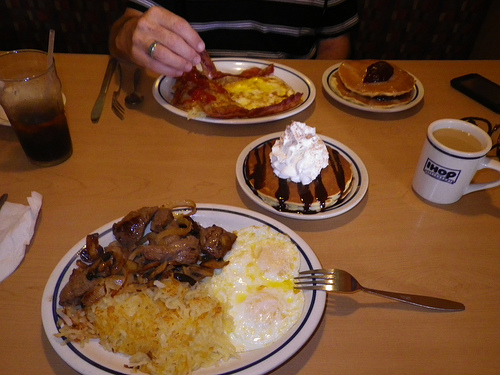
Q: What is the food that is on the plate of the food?
A: The food is eggs.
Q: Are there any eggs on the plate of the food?
A: Yes, there are eggs on the plate.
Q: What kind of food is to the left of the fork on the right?
A: The food is eggs.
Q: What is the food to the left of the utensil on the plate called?
A: The food is eggs.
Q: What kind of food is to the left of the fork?
A: The food is eggs.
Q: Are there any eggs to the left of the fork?
A: Yes, there are eggs to the left of the fork.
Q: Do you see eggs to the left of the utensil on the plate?
A: Yes, there are eggs to the left of the fork.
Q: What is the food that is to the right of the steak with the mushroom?
A: The food is eggs.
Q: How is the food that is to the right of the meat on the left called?
A: The food is eggs.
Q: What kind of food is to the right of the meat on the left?
A: The food is eggs.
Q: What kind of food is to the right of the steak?
A: The food is eggs.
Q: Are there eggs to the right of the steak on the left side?
A: Yes, there are eggs to the right of the steak.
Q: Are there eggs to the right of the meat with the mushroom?
A: Yes, there are eggs to the right of the steak.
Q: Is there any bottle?
A: No, there are no bottles.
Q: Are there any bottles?
A: No, there are no bottles.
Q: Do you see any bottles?
A: No, there are no bottles.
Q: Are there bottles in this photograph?
A: No, there are no bottles.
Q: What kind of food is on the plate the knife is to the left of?
A: The food is eggs.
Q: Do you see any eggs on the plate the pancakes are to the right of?
A: Yes, there are eggs on the plate.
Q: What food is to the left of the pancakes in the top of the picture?
A: The food is eggs.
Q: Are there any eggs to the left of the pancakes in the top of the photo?
A: Yes, there are eggs to the left of the pancakes.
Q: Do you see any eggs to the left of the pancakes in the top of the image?
A: Yes, there are eggs to the left of the pancakes.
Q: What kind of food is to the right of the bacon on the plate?
A: The food is eggs.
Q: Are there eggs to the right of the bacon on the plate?
A: Yes, there are eggs to the right of the bacon.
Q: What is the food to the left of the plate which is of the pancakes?
A: The food is eggs.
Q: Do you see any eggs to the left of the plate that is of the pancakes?
A: Yes, there are eggs to the left of the plate.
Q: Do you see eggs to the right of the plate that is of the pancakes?
A: No, the eggs are to the left of the plate.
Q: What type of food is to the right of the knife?
A: The food is eggs.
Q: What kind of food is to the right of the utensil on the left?
A: The food is eggs.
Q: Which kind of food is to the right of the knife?
A: The food is eggs.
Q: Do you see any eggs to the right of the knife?
A: Yes, there are eggs to the right of the knife.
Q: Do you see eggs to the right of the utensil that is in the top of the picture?
A: Yes, there are eggs to the right of the knife.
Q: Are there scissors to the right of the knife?
A: No, there are eggs to the right of the knife.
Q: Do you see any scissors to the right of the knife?
A: No, there are eggs to the right of the knife.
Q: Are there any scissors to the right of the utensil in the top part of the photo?
A: No, there are eggs to the right of the knife.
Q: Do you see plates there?
A: Yes, there is a plate.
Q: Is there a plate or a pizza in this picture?
A: Yes, there is a plate.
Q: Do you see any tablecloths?
A: No, there are no tablecloths.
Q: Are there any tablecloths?
A: No, there are no tablecloths.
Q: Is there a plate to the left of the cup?
A: Yes, there is a plate to the left of the cup.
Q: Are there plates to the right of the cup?
A: No, the plate is to the left of the cup.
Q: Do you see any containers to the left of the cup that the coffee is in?
A: No, there is a plate to the left of the cup.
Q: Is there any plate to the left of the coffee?
A: Yes, there is a plate to the left of the coffee.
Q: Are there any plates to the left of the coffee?
A: Yes, there is a plate to the left of the coffee.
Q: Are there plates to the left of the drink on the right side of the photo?
A: Yes, there is a plate to the left of the coffee.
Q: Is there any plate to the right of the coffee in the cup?
A: No, the plate is to the left of the coffee.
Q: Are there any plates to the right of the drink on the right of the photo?
A: No, the plate is to the left of the coffee.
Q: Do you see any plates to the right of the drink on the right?
A: No, the plate is to the left of the coffee.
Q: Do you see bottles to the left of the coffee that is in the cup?
A: No, there is a plate to the left of the coffee.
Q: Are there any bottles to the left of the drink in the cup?
A: No, there is a plate to the left of the coffee.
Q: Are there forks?
A: Yes, there is a fork.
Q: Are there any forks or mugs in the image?
A: Yes, there is a fork.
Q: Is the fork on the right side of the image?
A: Yes, the fork is on the right of the image.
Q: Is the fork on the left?
A: No, the fork is on the right of the image.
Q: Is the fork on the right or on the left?
A: The fork is on the right of the image.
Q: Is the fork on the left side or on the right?
A: The fork is on the right of the image.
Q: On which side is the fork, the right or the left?
A: The fork is on the right of the image.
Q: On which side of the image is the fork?
A: The fork is on the right of the image.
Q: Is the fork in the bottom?
A: Yes, the fork is in the bottom of the image.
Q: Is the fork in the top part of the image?
A: No, the fork is in the bottom of the image.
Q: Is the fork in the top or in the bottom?
A: The fork is in the bottom of the image.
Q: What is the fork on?
A: The fork is on the plate.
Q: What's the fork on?
A: The fork is on the plate.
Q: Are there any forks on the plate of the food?
A: Yes, there is a fork on the plate.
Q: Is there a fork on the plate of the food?
A: Yes, there is a fork on the plate.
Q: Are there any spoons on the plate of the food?
A: No, there is a fork on the plate.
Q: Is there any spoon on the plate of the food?
A: No, there is a fork on the plate.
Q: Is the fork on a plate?
A: Yes, the fork is on a plate.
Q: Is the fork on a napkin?
A: No, the fork is on a plate.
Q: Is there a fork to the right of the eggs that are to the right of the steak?
A: Yes, there is a fork to the right of the eggs.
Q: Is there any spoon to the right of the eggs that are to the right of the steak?
A: No, there is a fork to the right of the eggs.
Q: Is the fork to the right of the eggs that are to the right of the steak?
A: Yes, the fork is to the right of the eggs.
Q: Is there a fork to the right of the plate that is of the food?
A: Yes, there is a fork to the right of the plate.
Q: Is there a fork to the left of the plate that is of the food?
A: No, the fork is to the right of the plate.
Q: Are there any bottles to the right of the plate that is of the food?
A: No, there is a fork to the right of the plate.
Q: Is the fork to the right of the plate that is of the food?
A: Yes, the fork is to the right of the plate.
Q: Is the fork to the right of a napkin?
A: No, the fork is to the right of the plate.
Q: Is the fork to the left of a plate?
A: No, the fork is to the right of a plate.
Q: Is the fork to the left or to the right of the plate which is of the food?
A: The fork is to the right of the plate.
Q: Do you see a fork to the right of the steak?
A: Yes, there is a fork to the right of the steak.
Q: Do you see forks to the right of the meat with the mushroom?
A: Yes, there is a fork to the right of the steak.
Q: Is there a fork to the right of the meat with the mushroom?
A: Yes, there is a fork to the right of the steak.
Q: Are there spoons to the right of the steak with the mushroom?
A: No, there is a fork to the right of the steak.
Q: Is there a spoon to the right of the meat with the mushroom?
A: No, there is a fork to the right of the steak.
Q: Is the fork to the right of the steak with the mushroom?
A: Yes, the fork is to the right of the steak.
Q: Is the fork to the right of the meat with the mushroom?
A: Yes, the fork is to the right of the steak.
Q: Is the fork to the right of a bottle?
A: No, the fork is to the right of the steak.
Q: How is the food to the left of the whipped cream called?
A: The food is chocolate.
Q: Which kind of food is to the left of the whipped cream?
A: The food is chocolate.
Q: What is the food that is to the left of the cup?
A: The food is chocolate.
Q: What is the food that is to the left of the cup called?
A: The food is chocolate.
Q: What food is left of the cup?
A: The food is chocolate.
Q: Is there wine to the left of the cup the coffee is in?
A: No, there is chocolate to the left of the cup.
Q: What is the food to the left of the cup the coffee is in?
A: The food is chocolate.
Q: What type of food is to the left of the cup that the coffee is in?
A: The food is chocolate.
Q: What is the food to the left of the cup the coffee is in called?
A: The food is chocolate.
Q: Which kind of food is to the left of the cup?
A: The food is chocolate.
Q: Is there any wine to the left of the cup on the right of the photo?
A: No, there is chocolate to the left of the cup.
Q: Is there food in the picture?
A: Yes, there is food.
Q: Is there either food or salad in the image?
A: Yes, there is food.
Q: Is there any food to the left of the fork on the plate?
A: Yes, there is food to the left of the fork.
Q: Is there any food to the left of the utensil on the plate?
A: Yes, there is food to the left of the fork.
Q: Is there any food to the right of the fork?
A: No, the food is to the left of the fork.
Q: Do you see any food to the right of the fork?
A: No, the food is to the left of the fork.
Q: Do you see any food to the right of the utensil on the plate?
A: No, the food is to the left of the fork.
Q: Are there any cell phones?
A: Yes, there is a cell phone.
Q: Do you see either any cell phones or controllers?
A: Yes, there is a cell phone.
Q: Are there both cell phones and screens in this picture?
A: No, there is a cell phone but no screens.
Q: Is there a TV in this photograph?
A: No, there are no televisions.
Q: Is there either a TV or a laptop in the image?
A: No, there are no televisions or laptops.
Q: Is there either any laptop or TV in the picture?
A: No, there are no televisions or laptops.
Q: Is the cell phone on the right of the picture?
A: Yes, the cell phone is on the right of the image.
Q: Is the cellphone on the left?
A: No, the cellphone is on the right of the image.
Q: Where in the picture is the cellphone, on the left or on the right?
A: The cellphone is on the right of the image.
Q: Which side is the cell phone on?
A: The cell phone is on the right of the image.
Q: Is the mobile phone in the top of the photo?
A: Yes, the mobile phone is in the top of the image.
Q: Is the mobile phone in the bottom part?
A: No, the mobile phone is in the top of the image.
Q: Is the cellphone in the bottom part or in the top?
A: The cellphone is in the top of the image.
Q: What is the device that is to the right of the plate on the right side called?
A: The device is a cell phone.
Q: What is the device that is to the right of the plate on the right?
A: The device is a cell phone.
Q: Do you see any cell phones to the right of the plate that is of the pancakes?
A: Yes, there is a cell phone to the right of the plate.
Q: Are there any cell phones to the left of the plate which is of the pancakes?
A: No, the cell phone is to the right of the plate.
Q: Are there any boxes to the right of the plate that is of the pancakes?
A: No, there is a cell phone to the right of the plate.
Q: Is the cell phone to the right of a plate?
A: Yes, the cell phone is to the right of a plate.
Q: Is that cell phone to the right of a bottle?
A: No, the cell phone is to the right of a plate.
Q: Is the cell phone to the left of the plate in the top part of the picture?
A: No, the cell phone is to the right of the plate.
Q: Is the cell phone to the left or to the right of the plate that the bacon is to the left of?
A: The cell phone is to the right of the plate.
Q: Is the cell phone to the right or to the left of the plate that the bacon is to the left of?
A: The cell phone is to the right of the plate.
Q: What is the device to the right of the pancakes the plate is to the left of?
A: The device is a cell phone.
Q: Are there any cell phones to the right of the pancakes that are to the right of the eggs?
A: Yes, there is a cell phone to the right of the pancakes.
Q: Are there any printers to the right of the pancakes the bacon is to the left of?
A: No, there is a cell phone to the right of the pancakes.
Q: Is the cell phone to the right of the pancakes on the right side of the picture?
A: Yes, the cell phone is to the right of the pancakes.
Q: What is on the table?
A: The mobile phone is on the table.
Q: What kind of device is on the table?
A: The device is a cell phone.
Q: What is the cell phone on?
A: The cell phone is on the table.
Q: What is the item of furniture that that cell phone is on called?
A: The piece of furniture is a table.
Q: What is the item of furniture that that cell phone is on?
A: The piece of furniture is a table.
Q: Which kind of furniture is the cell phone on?
A: The cell phone is on the table.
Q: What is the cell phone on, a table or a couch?
A: The cell phone is on a table.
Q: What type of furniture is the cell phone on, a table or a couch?
A: The cell phone is on a table.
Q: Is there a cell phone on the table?
A: Yes, there is a cell phone on the table.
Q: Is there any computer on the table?
A: No, there is a cell phone on the table.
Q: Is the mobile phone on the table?
A: Yes, the mobile phone is on the table.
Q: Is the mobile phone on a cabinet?
A: No, the mobile phone is on the table.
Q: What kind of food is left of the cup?
A: The food is chocolate.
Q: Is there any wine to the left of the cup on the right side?
A: No, there is chocolate to the left of the cup.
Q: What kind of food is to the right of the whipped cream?
A: The food is chocolate.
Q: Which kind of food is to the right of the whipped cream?
A: The food is chocolate.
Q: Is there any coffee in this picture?
A: Yes, there is coffee.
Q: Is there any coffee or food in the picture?
A: Yes, there is coffee.